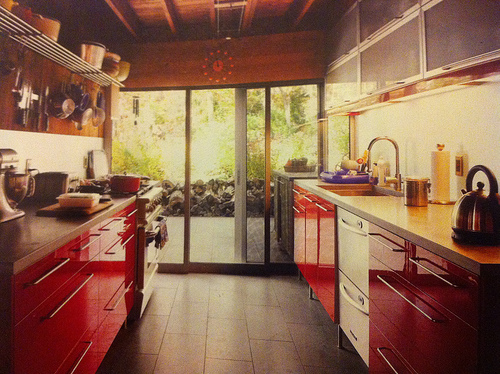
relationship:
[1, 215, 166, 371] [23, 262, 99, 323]
drawers with handles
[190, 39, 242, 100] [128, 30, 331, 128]
clock on wall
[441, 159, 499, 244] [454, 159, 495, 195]
kettle with a handle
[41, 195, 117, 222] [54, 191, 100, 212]
cutting board with a container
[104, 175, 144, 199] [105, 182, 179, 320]
pot on a stove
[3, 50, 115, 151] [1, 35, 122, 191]
pots hanging on wall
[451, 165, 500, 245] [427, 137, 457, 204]
kettle and paper towels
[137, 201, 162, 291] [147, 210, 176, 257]
door with a towel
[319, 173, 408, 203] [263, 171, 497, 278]
kitchen sink and countertop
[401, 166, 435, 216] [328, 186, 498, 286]
canister on counter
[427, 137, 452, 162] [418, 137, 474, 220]
holder with paper towels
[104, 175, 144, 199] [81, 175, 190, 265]
pot on stove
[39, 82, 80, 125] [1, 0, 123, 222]
pot hanging on wall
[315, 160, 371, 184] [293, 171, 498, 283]
holder on counter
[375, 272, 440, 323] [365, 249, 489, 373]
handle on drawer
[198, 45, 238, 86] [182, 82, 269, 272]
clock above door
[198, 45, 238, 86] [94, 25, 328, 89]
clock on wall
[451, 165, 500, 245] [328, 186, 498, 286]
kettle on counter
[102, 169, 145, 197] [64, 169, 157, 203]
pot on stove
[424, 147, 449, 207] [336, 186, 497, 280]
towels on counter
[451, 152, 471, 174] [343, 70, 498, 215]
outlet on wall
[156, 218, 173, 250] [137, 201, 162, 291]
towel hanging from door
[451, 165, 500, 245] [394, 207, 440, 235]
kettle sitting on countertop